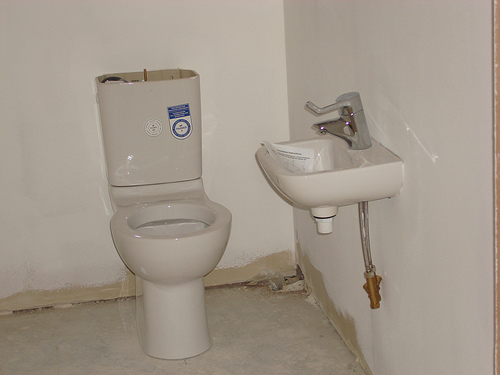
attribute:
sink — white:
[248, 127, 413, 240]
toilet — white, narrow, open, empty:
[82, 71, 247, 374]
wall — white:
[282, 2, 480, 367]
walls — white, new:
[6, 3, 496, 364]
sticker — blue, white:
[164, 101, 201, 151]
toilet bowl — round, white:
[104, 193, 250, 289]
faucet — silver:
[296, 86, 384, 153]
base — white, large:
[125, 273, 234, 361]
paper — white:
[260, 135, 320, 180]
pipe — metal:
[345, 192, 393, 283]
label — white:
[141, 116, 165, 145]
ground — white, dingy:
[10, 259, 366, 374]